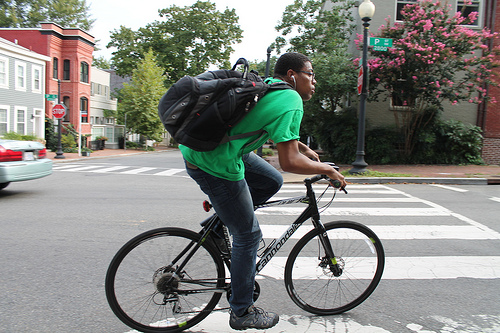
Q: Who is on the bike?
A: A man.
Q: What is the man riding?
A: A bicycle.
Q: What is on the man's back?
A: A backpack.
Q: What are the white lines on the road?
A: A crosswalk.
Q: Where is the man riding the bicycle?
A: Down a street.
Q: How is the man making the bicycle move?
A: He's pedaling.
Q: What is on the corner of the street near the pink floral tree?
A: A light post with signs.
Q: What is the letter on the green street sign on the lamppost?
A: P.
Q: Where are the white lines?
A: On street.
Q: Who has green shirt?
A: Bike rider.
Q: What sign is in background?
A: Stop sign.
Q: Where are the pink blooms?
A: Small tree.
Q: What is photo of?
A: Boy riding a bike.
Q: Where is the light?
A: On pole.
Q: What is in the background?
A: Buildings.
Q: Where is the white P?
A: On green street sign.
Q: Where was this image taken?
A: On a street.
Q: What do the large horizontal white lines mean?
A: They designate a crosswalk.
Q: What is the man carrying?
A: A backpack.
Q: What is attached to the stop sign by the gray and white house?
A: A sign with the name of the street.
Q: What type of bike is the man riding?
A: A mountain bike.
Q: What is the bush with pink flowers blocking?
A: A window.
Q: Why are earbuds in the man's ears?
A: He is listening to a music player.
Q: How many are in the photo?
A: One.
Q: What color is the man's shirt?
A: Green.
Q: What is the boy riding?
A: Bike.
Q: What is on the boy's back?
A: Bookbag.